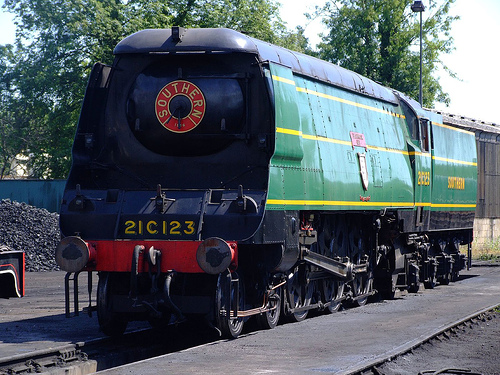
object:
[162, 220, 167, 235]
numbers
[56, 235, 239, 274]
bumper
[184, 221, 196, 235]
letters numbers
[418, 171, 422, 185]
letters numbers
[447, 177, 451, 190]
letters numbers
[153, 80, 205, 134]
circle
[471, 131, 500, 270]
wall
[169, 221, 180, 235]
train number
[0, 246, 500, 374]
ground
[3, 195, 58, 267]
rocks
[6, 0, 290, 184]
trees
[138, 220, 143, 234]
number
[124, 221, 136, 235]
number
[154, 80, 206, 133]
circle logo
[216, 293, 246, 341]
wheel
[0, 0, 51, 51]
blue sky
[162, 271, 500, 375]
sidewalk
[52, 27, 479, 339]
train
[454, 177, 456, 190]
word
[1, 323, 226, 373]
railroad track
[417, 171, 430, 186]
writing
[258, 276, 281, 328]
wheel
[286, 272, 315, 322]
wheel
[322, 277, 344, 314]
wheel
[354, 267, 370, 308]
wheel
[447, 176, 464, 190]
branding